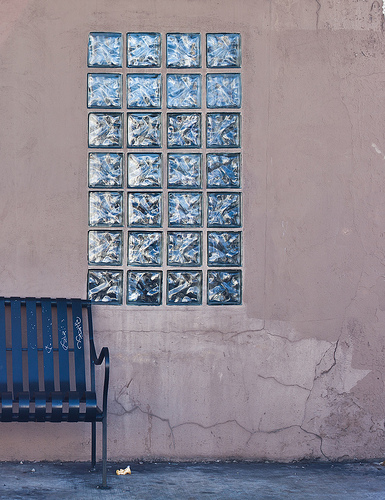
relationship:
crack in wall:
[107, 330, 349, 464] [0, 0, 383, 462]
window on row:
[84, 31, 241, 303] [87, 31, 241, 68]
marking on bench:
[73, 316, 84, 352] [2, 294, 114, 480]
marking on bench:
[58, 315, 69, 349] [2, 294, 114, 480]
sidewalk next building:
[220, 470, 331, 499] [1, 2, 377, 461]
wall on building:
[17, 7, 383, 350] [1, 2, 377, 461]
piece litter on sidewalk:
[115, 465, 131, 475] [1, 455, 383, 495]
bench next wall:
[2, 294, 114, 480] [255, 27, 352, 193]